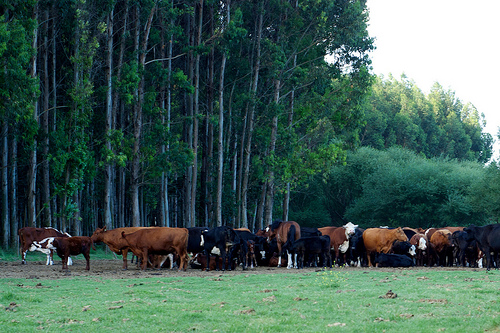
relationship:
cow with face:
[18, 222, 500, 272] [343, 221, 356, 237]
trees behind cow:
[5, 1, 375, 253] [18, 222, 500, 272]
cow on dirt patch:
[18, 222, 500, 272] [92, 269, 487, 280]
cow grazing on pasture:
[18, 222, 500, 272] [64, 263, 446, 317]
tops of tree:
[295, 1, 498, 209] [96, 27, 350, 197]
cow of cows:
[18, 222, 500, 272] [23, 226, 492, 274]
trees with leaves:
[5, 1, 375, 253] [260, 43, 363, 193]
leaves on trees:
[260, 43, 363, 193] [5, 1, 375, 253]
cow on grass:
[18, 222, 500, 272] [9, 275, 495, 331]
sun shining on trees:
[379, 17, 485, 151] [352, 72, 498, 213]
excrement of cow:
[365, 281, 396, 298] [30, 230, 104, 280]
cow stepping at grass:
[122, 222, 189, 277] [3, 252, 499, 332]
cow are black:
[18, 222, 500, 272] [191, 227, 261, 268]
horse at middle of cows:
[263, 221, 308, 261] [205, 218, 362, 268]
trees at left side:
[0, 0, 378, 251] [6, 15, 460, 210]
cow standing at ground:
[18, 222, 500, 272] [16, 260, 101, 272]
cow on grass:
[18, 222, 500, 272] [3, 252, 499, 332]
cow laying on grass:
[363, 250, 410, 266] [360, 247, 441, 289]